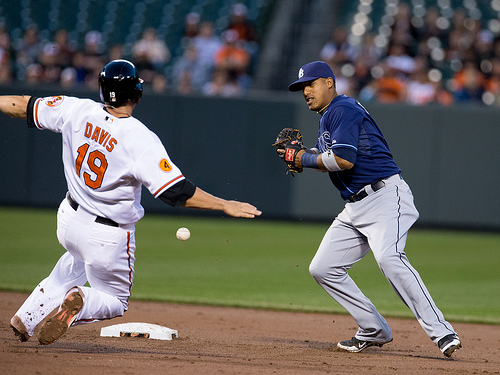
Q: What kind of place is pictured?
A: It is a stadium.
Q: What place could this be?
A: It is a stadium.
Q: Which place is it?
A: It is a stadium.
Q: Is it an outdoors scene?
A: Yes, it is outdoors.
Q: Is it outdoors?
A: Yes, it is outdoors.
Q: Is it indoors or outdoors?
A: It is outdoors.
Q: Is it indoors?
A: No, it is outdoors.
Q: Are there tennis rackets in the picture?
A: No, there are no tennis rackets.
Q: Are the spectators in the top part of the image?
A: Yes, the spectators are in the top of the image.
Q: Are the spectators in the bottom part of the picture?
A: No, the spectators are in the top of the image.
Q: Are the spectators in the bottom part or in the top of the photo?
A: The spectators are in the top of the image.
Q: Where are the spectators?
A: The spectators are at the game.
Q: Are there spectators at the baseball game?
A: Yes, there are spectators at the game.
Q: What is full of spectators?
A: The stadium is full of spectators.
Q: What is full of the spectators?
A: The stadium is full of spectators.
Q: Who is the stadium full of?
A: The stadium is full of spectators.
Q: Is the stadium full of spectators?
A: Yes, the stadium is full of spectators.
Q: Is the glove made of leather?
A: Yes, the glove is made of leather.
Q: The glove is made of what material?
A: The glove is made of leather.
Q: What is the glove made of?
A: The glove is made of leather.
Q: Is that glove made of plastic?
A: No, the glove is made of leather.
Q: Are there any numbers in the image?
A: Yes, there are numbers.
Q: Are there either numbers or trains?
A: Yes, there are numbers.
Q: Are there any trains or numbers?
A: Yes, there are numbers.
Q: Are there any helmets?
A: Yes, there is a helmet.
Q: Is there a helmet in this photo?
A: Yes, there is a helmet.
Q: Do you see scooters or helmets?
A: Yes, there is a helmet.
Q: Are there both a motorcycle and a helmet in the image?
A: No, there is a helmet but no motorcycles.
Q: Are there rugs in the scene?
A: No, there are no rugs.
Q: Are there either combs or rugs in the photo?
A: No, there are no rugs or combs.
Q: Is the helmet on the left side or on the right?
A: The helmet is on the left of the image.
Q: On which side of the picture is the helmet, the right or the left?
A: The helmet is on the left of the image.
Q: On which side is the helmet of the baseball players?
A: The helmet is on the left of the image.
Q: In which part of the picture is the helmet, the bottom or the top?
A: The helmet is in the top of the image.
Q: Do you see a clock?
A: No, there are no clocks.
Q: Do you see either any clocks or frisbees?
A: No, there are no clocks or frisbees.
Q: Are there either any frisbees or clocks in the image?
A: No, there are no clocks or frisbees.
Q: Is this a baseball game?
A: Yes, this is a baseball game.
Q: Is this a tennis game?
A: No, this is a baseball game.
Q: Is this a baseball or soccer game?
A: This is a baseball game.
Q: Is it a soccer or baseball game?
A: This is a baseball game.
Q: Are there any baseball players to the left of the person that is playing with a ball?
A: Yes, there are baseball players to the left of the person.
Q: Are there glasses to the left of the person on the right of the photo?
A: No, there are baseball players to the left of the person.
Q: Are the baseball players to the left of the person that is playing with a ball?
A: Yes, the baseball players are to the left of the person.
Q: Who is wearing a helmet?
A: The baseball players are wearing a helmet.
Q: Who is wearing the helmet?
A: The baseball players are wearing a helmet.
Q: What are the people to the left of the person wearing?
A: The baseball players are wearing a helmet.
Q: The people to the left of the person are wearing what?
A: The baseball players are wearing a helmet.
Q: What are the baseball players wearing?
A: The baseball players are wearing a helmet.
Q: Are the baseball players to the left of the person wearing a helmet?
A: Yes, the baseball players are wearing a helmet.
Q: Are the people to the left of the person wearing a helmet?
A: Yes, the baseball players are wearing a helmet.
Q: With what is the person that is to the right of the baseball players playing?
A: The person is playing with a ball.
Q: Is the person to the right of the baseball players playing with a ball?
A: Yes, the person is playing with a ball.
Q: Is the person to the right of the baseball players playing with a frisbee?
A: No, the person is playing with a ball.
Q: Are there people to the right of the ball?
A: Yes, there is a person to the right of the ball.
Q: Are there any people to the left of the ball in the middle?
A: No, the person is to the right of the ball.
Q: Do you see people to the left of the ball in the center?
A: No, the person is to the right of the ball.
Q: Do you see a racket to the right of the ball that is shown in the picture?
A: No, there is a person to the right of the ball.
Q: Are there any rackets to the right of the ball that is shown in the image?
A: No, there is a person to the right of the ball.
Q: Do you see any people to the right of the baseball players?
A: Yes, there is a person to the right of the baseball players.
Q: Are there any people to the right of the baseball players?
A: Yes, there is a person to the right of the baseball players.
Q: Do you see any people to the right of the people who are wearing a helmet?
A: Yes, there is a person to the right of the baseball players.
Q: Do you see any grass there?
A: Yes, there is grass.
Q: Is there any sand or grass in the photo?
A: Yes, there is grass.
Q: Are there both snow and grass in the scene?
A: No, there is grass but no snow.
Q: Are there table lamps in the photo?
A: No, there are no table lamps.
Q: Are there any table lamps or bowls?
A: No, there are no table lamps or bowls.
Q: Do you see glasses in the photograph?
A: No, there are no glasses.